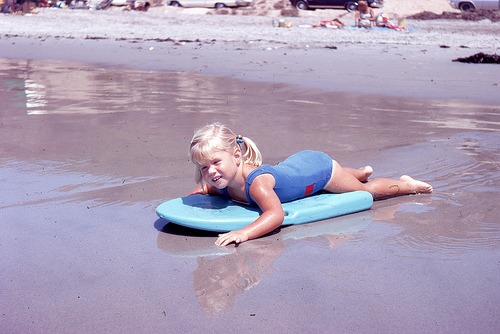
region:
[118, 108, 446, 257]
little girl on boogie board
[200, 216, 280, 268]
right arm of girl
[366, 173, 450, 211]
left leg of girl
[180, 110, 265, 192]
head of little girl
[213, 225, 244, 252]
hand of little girl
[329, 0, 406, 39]
people playing on beach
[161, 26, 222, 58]
rocks on beach on shore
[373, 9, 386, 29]
colored beach ball in sand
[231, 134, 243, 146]
ponytail holder in hair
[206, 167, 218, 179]
nose on little girl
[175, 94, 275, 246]
blond girl with ponytails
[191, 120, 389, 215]
blond girl in blue bathing suit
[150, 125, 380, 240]
child laying on small blue surfboard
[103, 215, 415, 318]
reflection of child in the water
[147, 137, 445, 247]
child's hand and feet are in the wet sand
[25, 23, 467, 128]
shoreline debris is behind the child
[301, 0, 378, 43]
woman sitting on beach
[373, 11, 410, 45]
woman has colorful beach ball next to her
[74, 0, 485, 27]
cars are parked in the distance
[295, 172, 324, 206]
child's swimming suit with red decoration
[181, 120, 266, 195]
the head of a girl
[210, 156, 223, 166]
the eye of a girl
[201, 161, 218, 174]
the nose of a girl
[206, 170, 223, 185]
the mouth of a girl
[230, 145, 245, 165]
the ear of a girl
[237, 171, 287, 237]
the arm of a girl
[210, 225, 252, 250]
the hand of a girl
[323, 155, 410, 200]
the leg of a girl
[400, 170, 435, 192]
the foot of a girl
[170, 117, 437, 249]
a girl on the beach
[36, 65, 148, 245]
the sand is smooth and grey.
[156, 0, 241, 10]
a white vehicle is parked.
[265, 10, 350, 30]
a blanket and belongings.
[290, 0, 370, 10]
a black car is parked along the beach.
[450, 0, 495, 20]
a grey car is parked in front of the sand.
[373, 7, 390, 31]
a red blue and white beach ball.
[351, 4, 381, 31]
a woman is wearing a blue and white beach dress.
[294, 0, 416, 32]
a woman is sitting in the sun.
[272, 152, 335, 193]
a little girl is wearing a blue bathing suit.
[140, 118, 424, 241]
a little girl is laying on the surfboard.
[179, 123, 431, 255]
a young girl laying down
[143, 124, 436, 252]
a young girl on surfboard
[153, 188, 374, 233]
a light surf board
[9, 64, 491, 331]
a brown wet sandy beach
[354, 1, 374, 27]
person sitting on beach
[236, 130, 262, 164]
a girl's pig tail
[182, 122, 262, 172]
a girl's blonde hair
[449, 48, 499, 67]
a patch of sea weed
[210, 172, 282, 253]
a girl's left arm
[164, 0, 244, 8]
a parked white car in distance